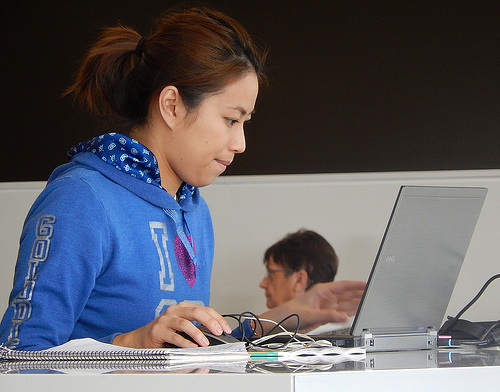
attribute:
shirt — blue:
[0, 130, 215, 355]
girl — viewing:
[0, 6, 270, 353]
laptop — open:
[251, 181, 491, 355]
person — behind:
[259, 227, 339, 311]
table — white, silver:
[1, 341, 500, 390]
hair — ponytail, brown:
[57, 6, 272, 126]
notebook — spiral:
[0, 337, 252, 364]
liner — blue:
[65, 129, 169, 192]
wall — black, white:
[0, 0, 499, 328]